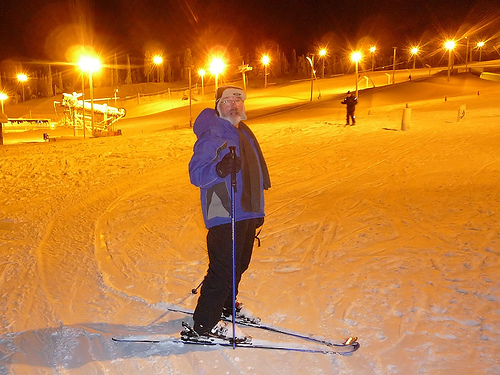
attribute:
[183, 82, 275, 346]
man — skiing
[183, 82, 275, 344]
skier — posing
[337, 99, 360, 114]
attire — black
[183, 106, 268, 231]
jacket — blue, gray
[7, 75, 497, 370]
ski slope — snow covered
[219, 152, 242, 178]
glove — black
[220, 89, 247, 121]
head — man's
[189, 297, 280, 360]
tracks — ski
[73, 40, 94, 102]
post — shining, light, brightly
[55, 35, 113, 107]
post — brightly, shining, light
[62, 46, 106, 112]
post — light, shining, brightly